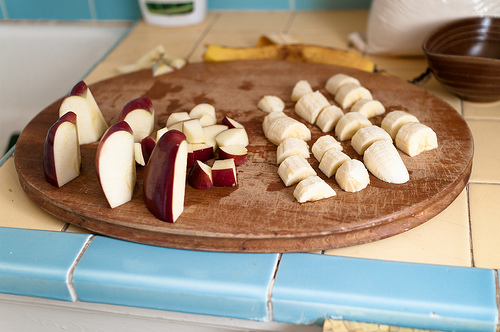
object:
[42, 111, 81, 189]
apple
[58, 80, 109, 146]
apple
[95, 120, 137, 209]
apple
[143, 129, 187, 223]
apple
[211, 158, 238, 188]
apple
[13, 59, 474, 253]
board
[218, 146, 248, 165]
apple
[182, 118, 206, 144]
apple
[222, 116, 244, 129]
apple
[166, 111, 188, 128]
apple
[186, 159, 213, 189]
apple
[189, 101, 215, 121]
apple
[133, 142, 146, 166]
apple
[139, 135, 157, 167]
apple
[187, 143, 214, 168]
apple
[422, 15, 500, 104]
bowl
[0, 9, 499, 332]
counter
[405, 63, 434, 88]
crack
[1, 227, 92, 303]
tile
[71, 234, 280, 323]
tile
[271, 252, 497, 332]
tile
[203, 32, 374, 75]
peel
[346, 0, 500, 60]
bag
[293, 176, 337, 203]
banana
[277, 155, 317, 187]
banana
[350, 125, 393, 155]
banana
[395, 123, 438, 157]
banana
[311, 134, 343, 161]
banana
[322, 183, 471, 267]
tile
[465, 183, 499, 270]
tile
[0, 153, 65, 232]
tile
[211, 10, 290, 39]
tile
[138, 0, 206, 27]
bottle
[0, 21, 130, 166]
sink